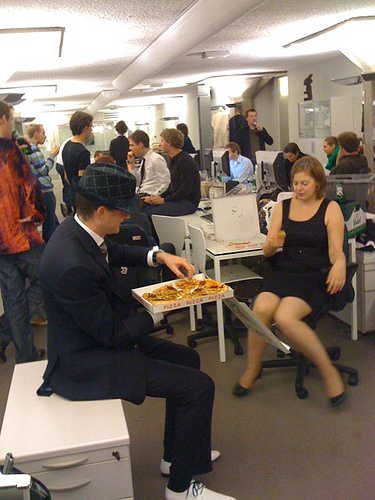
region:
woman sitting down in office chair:
[234, 152, 358, 407]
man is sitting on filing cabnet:
[0, 162, 214, 498]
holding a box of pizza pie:
[133, 269, 291, 355]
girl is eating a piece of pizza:
[256, 215, 294, 263]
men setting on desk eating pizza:
[119, 125, 199, 242]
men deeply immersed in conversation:
[61, 108, 200, 237]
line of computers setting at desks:
[181, 145, 296, 208]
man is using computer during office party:
[199, 142, 257, 192]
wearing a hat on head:
[73, 162, 142, 218]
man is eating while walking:
[236, 106, 274, 163]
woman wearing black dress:
[285, 151, 347, 400]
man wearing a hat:
[72, 163, 245, 496]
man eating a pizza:
[79, 153, 226, 498]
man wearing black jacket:
[54, 159, 249, 496]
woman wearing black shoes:
[291, 156, 358, 400]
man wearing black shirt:
[152, 123, 197, 219]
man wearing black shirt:
[71, 106, 90, 171]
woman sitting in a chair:
[290, 151, 359, 386]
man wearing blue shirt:
[232, 137, 249, 173]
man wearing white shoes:
[40, 155, 225, 497]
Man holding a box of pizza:
[38, 162, 238, 497]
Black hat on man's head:
[61, 163, 142, 216]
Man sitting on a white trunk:
[0, 163, 236, 498]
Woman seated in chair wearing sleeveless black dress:
[231, 157, 355, 407]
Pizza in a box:
[129, 271, 235, 313]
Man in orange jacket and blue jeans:
[0, 102, 43, 357]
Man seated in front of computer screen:
[251, 140, 311, 188]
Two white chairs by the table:
[149, 213, 211, 327]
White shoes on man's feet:
[158, 449, 228, 498]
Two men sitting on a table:
[126, 127, 203, 224]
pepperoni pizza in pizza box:
[136, 272, 234, 318]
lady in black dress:
[227, 152, 356, 413]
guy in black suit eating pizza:
[42, 151, 238, 492]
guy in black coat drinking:
[242, 105, 273, 153]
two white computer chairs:
[147, 205, 207, 269]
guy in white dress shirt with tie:
[124, 122, 170, 208]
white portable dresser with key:
[8, 365, 143, 497]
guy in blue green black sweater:
[25, 121, 67, 199]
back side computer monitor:
[198, 150, 233, 181]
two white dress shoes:
[157, 450, 241, 498]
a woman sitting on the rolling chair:
[232, 154, 358, 406]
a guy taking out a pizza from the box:
[37, 162, 290, 498]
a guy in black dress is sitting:
[38, 160, 235, 498]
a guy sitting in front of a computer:
[200, 144, 256, 190]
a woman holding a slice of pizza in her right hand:
[232, 156, 348, 406]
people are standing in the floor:
[0, 103, 94, 366]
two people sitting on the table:
[128, 127, 219, 267]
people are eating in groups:
[21, 112, 232, 399]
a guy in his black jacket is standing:
[233, 108, 273, 196]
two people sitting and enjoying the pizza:
[38, 154, 349, 495]